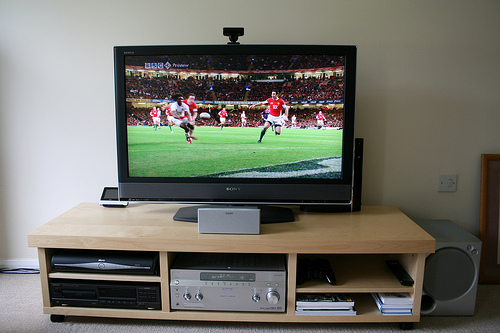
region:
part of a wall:
[450, 81, 465, 92]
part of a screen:
[327, 160, 339, 195]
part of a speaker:
[421, 290, 446, 329]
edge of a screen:
[302, 155, 318, 187]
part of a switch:
[428, 187, 440, 191]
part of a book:
[333, 298, 343, 313]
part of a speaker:
[236, 193, 245, 222]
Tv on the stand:
[99, 35, 362, 227]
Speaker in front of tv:
[188, 200, 265, 240]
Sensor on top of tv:
[214, 18, 247, 47]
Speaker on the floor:
[413, 218, 487, 321]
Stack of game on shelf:
[292, 295, 357, 322]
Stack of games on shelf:
[373, 293, 415, 320]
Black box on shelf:
[47, 247, 159, 282]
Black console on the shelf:
[45, 275, 160, 319]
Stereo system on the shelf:
[163, 262, 284, 319]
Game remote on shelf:
[291, 251, 340, 287]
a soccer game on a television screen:
[122, 50, 347, 182]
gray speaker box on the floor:
[409, 211, 485, 321]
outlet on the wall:
[433, 169, 460, 195]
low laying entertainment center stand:
[32, 201, 436, 331]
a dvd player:
[43, 249, 168, 283]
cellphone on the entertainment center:
[100, 183, 128, 213]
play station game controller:
[294, 262, 343, 286]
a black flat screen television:
[114, 24, 354, 221]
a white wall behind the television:
[0, 1, 496, 273]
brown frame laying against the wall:
[474, 143, 499, 285]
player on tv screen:
[258, 83, 292, 130]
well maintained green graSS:
[160, 130, 240, 163]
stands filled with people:
[152, 70, 255, 92]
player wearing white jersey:
[157, 101, 199, 118]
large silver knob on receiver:
[263, 287, 283, 304]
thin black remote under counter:
[378, 255, 409, 290]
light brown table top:
[307, 210, 417, 247]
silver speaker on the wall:
[413, 216, 485, 312]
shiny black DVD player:
[52, 253, 157, 277]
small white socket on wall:
[424, 170, 469, 193]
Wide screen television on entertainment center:
[109, 43, 359, 202]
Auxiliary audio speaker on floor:
[418, 216, 477, 314]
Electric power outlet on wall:
[437, 173, 458, 195]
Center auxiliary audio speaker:
[196, 205, 263, 236]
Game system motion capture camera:
[217, 24, 249, 42]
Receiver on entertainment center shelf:
[168, 268, 289, 313]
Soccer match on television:
[124, 55, 341, 179]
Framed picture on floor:
[474, 148, 498, 297]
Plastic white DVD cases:
[294, 295, 359, 319]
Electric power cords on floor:
[0, 263, 41, 275]